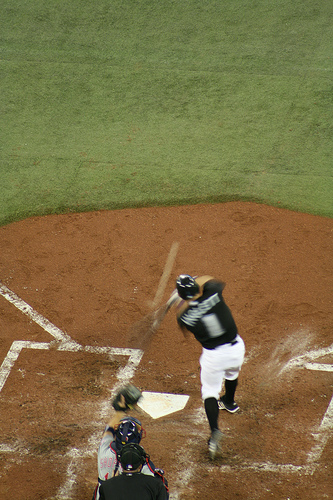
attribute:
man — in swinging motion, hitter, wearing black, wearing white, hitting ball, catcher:
[174, 271, 246, 461]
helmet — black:
[175, 273, 200, 302]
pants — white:
[199, 328, 245, 400]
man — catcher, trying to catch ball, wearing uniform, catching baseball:
[96, 385, 161, 491]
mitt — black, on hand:
[110, 382, 141, 410]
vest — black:
[110, 442, 154, 473]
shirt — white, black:
[177, 277, 238, 349]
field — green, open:
[2, 2, 332, 499]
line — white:
[1, 281, 149, 499]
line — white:
[168, 332, 332, 500]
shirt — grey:
[93, 433, 154, 500]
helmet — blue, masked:
[116, 419, 143, 445]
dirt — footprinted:
[2, 197, 329, 500]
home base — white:
[133, 389, 192, 422]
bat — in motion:
[132, 294, 179, 345]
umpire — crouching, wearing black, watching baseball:
[99, 446, 169, 499]